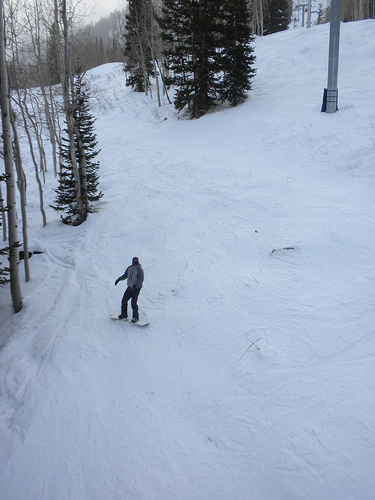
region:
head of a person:
[126, 243, 149, 267]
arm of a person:
[115, 267, 130, 287]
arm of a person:
[131, 270, 150, 287]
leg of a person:
[113, 287, 131, 313]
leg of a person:
[123, 292, 157, 317]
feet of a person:
[109, 313, 130, 324]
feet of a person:
[124, 308, 154, 331]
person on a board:
[94, 224, 174, 336]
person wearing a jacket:
[88, 242, 185, 343]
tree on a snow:
[27, 47, 115, 235]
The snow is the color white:
[142, 138, 336, 225]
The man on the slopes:
[103, 233, 170, 328]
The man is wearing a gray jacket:
[113, 253, 148, 291]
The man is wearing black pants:
[114, 287, 145, 317]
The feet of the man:
[115, 310, 142, 322]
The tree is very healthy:
[169, 2, 256, 112]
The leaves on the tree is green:
[172, 6, 242, 99]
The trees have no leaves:
[2, 5, 79, 279]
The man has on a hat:
[126, 252, 145, 271]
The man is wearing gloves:
[113, 275, 138, 296]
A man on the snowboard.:
[102, 251, 153, 345]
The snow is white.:
[40, 365, 310, 464]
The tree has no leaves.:
[12, 10, 68, 117]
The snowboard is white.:
[109, 306, 169, 336]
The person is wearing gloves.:
[110, 274, 123, 289]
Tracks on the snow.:
[128, 146, 221, 227]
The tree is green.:
[156, 2, 265, 114]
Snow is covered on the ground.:
[125, 143, 329, 211]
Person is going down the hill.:
[109, 247, 150, 342]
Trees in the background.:
[23, 2, 150, 61]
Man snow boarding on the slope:
[103, 244, 159, 334]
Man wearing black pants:
[117, 281, 142, 320]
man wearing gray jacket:
[111, 261, 148, 293]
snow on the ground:
[102, 351, 262, 462]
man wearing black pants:
[127, 283, 140, 294]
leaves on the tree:
[165, 3, 242, 106]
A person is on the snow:
[106, 253, 216, 359]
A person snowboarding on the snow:
[103, 251, 233, 382]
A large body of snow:
[65, 352, 257, 497]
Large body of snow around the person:
[77, 233, 281, 437]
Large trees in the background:
[121, 3, 257, 126]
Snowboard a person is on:
[105, 307, 148, 330]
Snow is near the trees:
[104, 52, 234, 166]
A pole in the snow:
[312, 8, 367, 143]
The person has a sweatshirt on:
[111, 253, 153, 293]